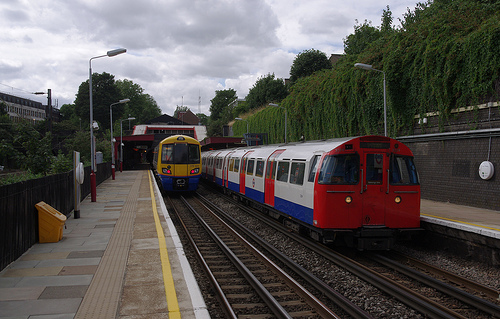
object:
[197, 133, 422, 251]
train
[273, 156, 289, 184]
window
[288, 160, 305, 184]
window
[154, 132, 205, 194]
train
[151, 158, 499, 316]
tracks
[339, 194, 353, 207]
headlights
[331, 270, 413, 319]
gravel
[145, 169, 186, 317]
line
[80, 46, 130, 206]
light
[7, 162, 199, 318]
platform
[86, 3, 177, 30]
cloud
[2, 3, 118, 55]
sky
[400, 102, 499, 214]
wall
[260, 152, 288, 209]
door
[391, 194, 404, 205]
light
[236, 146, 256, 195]
door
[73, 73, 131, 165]
tree